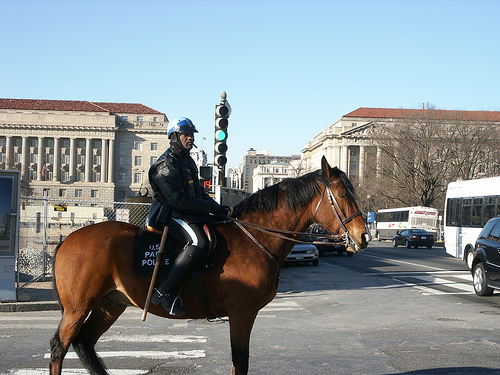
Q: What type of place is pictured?
A: It is a street.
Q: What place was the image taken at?
A: It was taken at the street.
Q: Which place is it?
A: It is a street.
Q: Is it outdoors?
A: Yes, it is outdoors.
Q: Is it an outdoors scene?
A: Yes, it is outdoors.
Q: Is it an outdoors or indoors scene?
A: It is outdoors.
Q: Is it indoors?
A: No, it is outdoors.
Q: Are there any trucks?
A: No, there are no trucks.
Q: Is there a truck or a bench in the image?
A: No, there are no trucks or benches.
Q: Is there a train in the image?
A: No, there are no trains.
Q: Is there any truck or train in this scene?
A: No, there are no trains or trucks.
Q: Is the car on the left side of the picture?
A: No, the car is on the right of the image.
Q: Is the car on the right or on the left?
A: The car is on the right of the image.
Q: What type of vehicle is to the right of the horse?
A: The vehicle is a car.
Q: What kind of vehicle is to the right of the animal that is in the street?
A: The vehicle is a car.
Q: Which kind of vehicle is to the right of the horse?
A: The vehicle is a car.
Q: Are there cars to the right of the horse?
A: Yes, there is a car to the right of the horse.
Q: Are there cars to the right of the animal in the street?
A: Yes, there is a car to the right of the horse.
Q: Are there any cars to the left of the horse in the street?
A: No, the car is to the right of the horse.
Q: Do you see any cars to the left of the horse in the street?
A: No, the car is to the right of the horse.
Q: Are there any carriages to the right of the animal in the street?
A: No, there is a car to the right of the horse.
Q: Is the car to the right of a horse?
A: Yes, the car is to the right of a horse.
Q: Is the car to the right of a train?
A: No, the car is to the right of a horse.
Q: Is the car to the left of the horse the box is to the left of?
A: No, the car is to the right of the horse.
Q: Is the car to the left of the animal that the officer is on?
A: No, the car is to the right of the horse.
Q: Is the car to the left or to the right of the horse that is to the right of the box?
A: The car is to the right of the horse.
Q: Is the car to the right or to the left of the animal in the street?
A: The car is to the right of the horse.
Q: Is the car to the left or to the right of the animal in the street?
A: The car is to the right of the horse.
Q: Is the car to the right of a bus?
A: No, the car is to the left of a bus.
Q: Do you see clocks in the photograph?
A: No, there are no clocks.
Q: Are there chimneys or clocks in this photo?
A: No, there are no clocks or chimneys.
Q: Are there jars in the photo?
A: No, there are no jars.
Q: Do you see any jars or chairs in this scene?
A: No, there are no jars or chairs.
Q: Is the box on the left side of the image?
A: Yes, the box is on the left of the image.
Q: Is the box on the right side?
A: No, the box is on the left of the image.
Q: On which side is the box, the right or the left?
A: The box is on the left of the image.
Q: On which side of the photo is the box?
A: The box is on the left of the image.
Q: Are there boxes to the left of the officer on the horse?
A: Yes, there is a box to the left of the officer.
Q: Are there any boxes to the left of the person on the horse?
A: Yes, there is a box to the left of the officer.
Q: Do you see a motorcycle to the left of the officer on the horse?
A: No, there is a box to the left of the officer.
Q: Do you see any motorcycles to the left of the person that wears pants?
A: No, there is a box to the left of the officer.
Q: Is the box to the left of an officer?
A: Yes, the box is to the left of an officer.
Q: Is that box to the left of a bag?
A: No, the box is to the left of an officer.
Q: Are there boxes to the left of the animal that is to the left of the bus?
A: Yes, there is a box to the left of the horse.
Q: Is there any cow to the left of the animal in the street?
A: No, there is a box to the left of the horse.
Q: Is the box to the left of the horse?
A: Yes, the box is to the left of the horse.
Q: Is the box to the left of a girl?
A: No, the box is to the left of the horse.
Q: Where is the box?
A: The box is on the sidewalk.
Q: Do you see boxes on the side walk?
A: Yes, there is a box on the side walk.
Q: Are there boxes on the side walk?
A: Yes, there is a box on the side walk.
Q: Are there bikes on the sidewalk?
A: No, there is a box on the sidewalk.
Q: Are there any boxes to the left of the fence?
A: Yes, there is a box to the left of the fence.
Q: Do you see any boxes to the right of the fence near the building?
A: No, the box is to the left of the fence.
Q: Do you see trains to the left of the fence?
A: No, there is a box to the left of the fence.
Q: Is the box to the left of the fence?
A: Yes, the box is to the left of the fence.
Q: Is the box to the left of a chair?
A: No, the box is to the left of the fence.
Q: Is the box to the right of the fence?
A: No, the box is to the left of the fence.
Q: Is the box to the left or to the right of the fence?
A: The box is to the left of the fence.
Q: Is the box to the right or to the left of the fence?
A: The box is to the left of the fence.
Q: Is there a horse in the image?
A: Yes, there is a horse.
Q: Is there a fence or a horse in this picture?
A: Yes, there is a horse.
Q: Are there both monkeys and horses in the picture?
A: No, there is a horse but no monkeys.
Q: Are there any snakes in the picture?
A: No, there are no snakes.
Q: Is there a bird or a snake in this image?
A: No, there are no snakes or birds.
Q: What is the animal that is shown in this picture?
A: The animal is a horse.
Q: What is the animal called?
A: The animal is a horse.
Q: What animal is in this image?
A: The animal is a horse.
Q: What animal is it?
A: The animal is a horse.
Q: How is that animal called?
A: This is a horse.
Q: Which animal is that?
A: This is a horse.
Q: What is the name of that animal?
A: This is a horse.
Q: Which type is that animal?
A: This is a horse.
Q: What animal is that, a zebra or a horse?
A: This is a horse.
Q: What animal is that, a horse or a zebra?
A: This is a horse.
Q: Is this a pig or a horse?
A: This is a horse.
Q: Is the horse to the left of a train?
A: No, the horse is to the left of a bus.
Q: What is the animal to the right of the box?
A: The animal is a horse.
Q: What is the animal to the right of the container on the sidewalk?
A: The animal is a horse.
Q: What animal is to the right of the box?
A: The animal is a horse.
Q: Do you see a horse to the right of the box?
A: Yes, there is a horse to the right of the box.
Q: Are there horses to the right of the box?
A: Yes, there is a horse to the right of the box.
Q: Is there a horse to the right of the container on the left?
A: Yes, there is a horse to the right of the box.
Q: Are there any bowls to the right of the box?
A: No, there is a horse to the right of the box.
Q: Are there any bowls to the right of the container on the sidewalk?
A: No, there is a horse to the right of the box.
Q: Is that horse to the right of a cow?
A: No, the horse is to the right of a box.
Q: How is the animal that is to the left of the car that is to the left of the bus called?
A: The animal is a horse.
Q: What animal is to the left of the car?
A: The animal is a horse.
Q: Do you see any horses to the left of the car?
A: Yes, there is a horse to the left of the car.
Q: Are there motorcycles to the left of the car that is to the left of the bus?
A: No, there is a horse to the left of the car.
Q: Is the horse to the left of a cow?
A: No, the horse is to the left of the car.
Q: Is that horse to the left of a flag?
A: No, the horse is to the left of a bus.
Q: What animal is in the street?
A: The horse is in the street.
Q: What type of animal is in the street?
A: The animal is a horse.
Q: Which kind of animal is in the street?
A: The animal is a horse.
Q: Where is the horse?
A: The horse is in the street.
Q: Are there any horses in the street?
A: Yes, there is a horse in the street.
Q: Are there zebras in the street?
A: No, there is a horse in the street.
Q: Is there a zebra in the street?
A: No, there is a horse in the street.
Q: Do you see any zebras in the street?
A: No, there is a horse in the street.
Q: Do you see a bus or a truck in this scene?
A: Yes, there is a bus.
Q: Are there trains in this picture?
A: No, there are no trains.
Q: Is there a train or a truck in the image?
A: No, there are no trains or trucks.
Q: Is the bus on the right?
A: Yes, the bus is on the right of the image.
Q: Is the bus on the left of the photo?
A: No, the bus is on the right of the image.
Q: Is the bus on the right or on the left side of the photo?
A: The bus is on the right of the image.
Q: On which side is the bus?
A: The bus is on the right of the image.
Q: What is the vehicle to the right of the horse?
A: The vehicle is a bus.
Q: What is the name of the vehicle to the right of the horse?
A: The vehicle is a bus.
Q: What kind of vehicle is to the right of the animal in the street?
A: The vehicle is a bus.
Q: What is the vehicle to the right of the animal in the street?
A: The vehicle is a bus.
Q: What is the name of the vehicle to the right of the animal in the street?
A: The vehicle is a bus.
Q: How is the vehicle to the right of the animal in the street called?
A: The vehicle is a bus.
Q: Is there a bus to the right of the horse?
A: Yes, there is a bus to the right of the horse.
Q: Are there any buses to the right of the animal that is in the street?
A: Yes, there is a bus to the right of the horse.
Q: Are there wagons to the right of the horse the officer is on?
A: No, there is a bus to the right of the horse.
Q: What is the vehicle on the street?
A: The vehicle is a bus.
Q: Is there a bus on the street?
A: Yes, there is a bus on the street.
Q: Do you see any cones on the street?
A: No, there is a bus on the street.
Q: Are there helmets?
A: Yes, there is a helmet.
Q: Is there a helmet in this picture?
A: Yes, there is a helmet.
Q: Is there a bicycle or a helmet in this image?
A: Yes, there is a helmet.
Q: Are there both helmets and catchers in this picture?
A: No, there is a helmet but no catchers.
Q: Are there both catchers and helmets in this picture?
A: No, there is a helmet but no catchers.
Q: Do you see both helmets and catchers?
A: No, there is a helmet but no catchers.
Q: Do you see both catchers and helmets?
A: No, there is a helmet but no catchers.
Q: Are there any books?
A: No, there are no books.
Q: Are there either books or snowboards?
A: No, there are no books or snowboards.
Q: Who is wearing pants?
A: The officer is wearing pants.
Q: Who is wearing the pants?
A: The officer is wearing pants.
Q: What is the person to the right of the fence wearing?
A: The officer is wearing pants.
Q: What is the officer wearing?
A: The officer is wearing pants.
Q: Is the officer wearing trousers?
A: Yes, the officer is wearing trousers.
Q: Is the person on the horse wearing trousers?
A: Yes, the officer is wearing trousers.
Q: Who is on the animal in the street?
A: The officer is on the horse.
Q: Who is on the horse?
A: The officer is on the horse.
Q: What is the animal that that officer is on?
A: The animal is a horse.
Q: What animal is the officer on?
A: The officer is on the horse.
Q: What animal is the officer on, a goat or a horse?
A: The officer is on a horse.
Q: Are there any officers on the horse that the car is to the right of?
A: Yes, there is an officer on the horse.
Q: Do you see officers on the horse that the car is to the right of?
A: Yes, there is an officer on the horse.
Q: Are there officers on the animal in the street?
A: Yes, there is an officer on the horse.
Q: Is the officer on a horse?
A: Yes, the officer is on a horse.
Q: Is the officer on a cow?
A: No, the officer is on a horse.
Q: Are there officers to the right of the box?
A: Yes, there is an officer to the right of the box.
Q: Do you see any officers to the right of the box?
A: Yes, there is an officer to the right of the box.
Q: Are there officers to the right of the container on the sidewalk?
A: Yes, there is an officer to the right of the box.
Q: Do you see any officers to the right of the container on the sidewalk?
A: Yes, there is an officer to the right of the box.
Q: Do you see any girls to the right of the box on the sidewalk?
A: No, there is an officer to the right of the box.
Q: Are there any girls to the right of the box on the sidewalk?
A: No, there is an officer to the right of the box.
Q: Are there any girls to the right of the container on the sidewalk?
A: No, there is an officer to the right of the box.